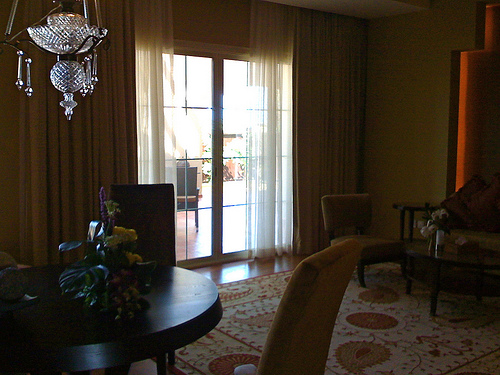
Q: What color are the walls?
A: Olive green.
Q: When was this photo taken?
A: During the day.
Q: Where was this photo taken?
A: In the dining room.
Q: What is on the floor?
A: A nice area rug.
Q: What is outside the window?
A: A chair.